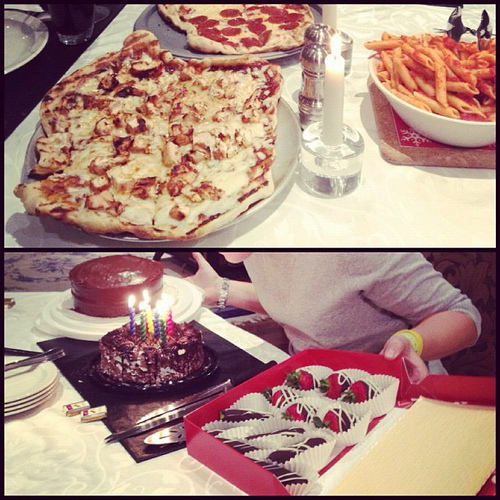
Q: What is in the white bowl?
A: Pasta.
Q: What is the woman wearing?
A: Grey shirt.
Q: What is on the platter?
A: Cake.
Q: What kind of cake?
A: Chocolate.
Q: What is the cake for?
A: Birthday.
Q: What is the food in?
A: Red case.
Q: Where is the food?
A: Table.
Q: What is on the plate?
A: Pizza.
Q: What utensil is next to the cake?
A: Knife.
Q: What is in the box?
A: Cupcakes.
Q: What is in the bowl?
A: Noodles.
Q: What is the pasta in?
A: A bowl.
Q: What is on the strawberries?
A: Chocolate.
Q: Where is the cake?
A: On a plate.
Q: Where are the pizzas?
A: On plates.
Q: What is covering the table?
A: Table cloth.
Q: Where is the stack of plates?
A: Next to the birthday cake.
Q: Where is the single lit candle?
A: Next to the pizza.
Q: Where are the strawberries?
A: In a box.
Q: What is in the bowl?
A: Pasta.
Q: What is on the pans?
A: Pizza.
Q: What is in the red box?
A: Dessert.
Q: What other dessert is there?
A: Cake.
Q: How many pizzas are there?
A: Two.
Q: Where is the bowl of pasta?
A: On the table.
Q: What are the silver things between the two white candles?
A: Salt and pepper shakers.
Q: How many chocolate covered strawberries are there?
A: Six.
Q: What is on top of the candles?
A: Fire.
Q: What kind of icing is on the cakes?
A: Chocolate.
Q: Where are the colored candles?
A: On top of the cake.